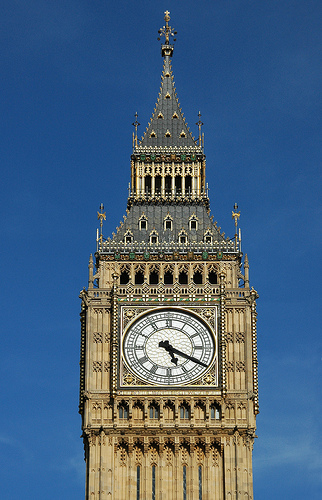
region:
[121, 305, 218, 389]
clock on the tower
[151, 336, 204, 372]
black hands on clock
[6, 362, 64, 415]
blue sky behind clock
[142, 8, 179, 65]
tip of the tower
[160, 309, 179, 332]
roman numeral on clock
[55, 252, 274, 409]
brown tower with white face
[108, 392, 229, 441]
windows on the building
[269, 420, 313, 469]
cloud in the sky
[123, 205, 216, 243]
seven windows on tower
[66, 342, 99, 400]
edge of the tower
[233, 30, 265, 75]
part of the sky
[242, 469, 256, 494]
edge of a tower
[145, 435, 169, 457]
part of a tower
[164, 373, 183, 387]
edge of a clock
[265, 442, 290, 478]
part of a cloud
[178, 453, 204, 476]
part of a tower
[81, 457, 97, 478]
edge of a tower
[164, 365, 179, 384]
part of a clock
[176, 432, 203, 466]
part of a tower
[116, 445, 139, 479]
part of a tower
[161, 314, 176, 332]
Enumeral number twelve on clock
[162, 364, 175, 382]
Enumeral number six on clock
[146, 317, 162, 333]
Enumeral number eleven on clock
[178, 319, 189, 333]
Enumeral number one on clock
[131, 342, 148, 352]
Enumeral number nine on clock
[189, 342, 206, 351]
Enumeral number three on clock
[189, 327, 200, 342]
Enumeral number two on clock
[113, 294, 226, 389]
White clock on building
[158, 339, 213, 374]
Hands on face of clock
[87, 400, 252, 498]
Bottom of brick building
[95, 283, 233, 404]
a clock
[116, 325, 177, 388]
a clock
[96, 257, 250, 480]
a clock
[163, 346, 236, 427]
a clock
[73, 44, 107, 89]
part of the sky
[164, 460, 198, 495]
part of a tower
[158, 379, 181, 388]
edge of a clock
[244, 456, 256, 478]
edge of a tower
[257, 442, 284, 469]
part of a cloud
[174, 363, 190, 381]
part of a clock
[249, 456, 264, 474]
edge of a tower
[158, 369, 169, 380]
part of a clock